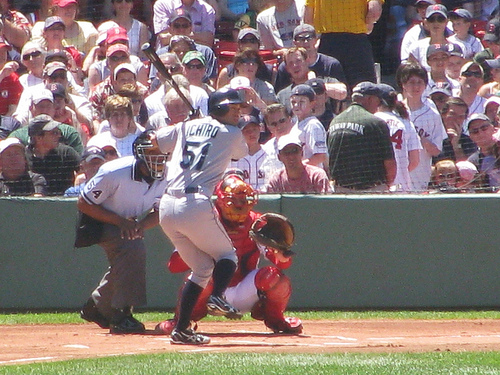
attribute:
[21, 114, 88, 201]
spectator — in stands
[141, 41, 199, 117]
bat — black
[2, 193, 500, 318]
wall — green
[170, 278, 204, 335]
sock — long, black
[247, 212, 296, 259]
baseball glove — brown, leather, black, red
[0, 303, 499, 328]
grass — green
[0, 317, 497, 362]
dirt — red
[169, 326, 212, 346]
sneaker — black, white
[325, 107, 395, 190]
shirt — green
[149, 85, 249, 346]
baseball player — batting, playing baseball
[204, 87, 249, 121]
helmet — black, shiny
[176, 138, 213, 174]
number — black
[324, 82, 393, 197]
fan — facing away, standing up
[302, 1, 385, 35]
shirt — yellow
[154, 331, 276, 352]
box — batters box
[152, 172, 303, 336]
catcher — red sox catcher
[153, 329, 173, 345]
plate — home plate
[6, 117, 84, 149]
shirt — green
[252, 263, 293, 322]
shin guard — red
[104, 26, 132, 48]
cap — red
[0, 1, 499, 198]
spectators — watching baseball